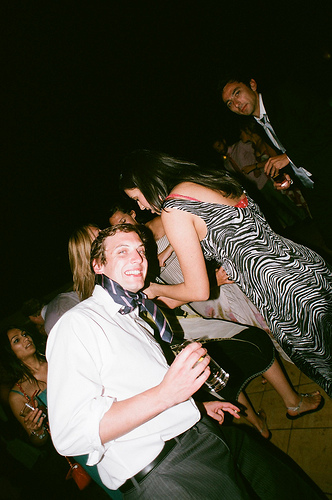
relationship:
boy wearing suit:
[37, 222, 326, 494] [44, 274, 330, 497]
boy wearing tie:
[37, 222, 326, 494] [92, 270, 173, 344]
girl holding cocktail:
[0, 325, 126, 497] [20, 400, 46, 418]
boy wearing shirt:
[45, 223, 326, 498] [43, 286, 208, 490]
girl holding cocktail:
[0, 325, 126, 497] [20, 400, 49, 425]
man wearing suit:
[213, 72, 331, 243] [259, 92, 331, 227]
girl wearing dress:
[118, 148, 332, 395] [160, 197, 328, 397]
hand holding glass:
[152, 341, 219, 412] [197, 363, 235, 396]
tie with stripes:
[94, 272, 175, 344] [158, 319, 170, 331]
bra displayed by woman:
[167, 191, 210, 209] [159, 179, 313, 287]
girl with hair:
[0, 325, 126, 497] [0, 351, 30, 374]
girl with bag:
[0, 325, 126, 497] [68, 461, 91, 490]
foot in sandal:
[305, 391, 322, 410] [290, 391, 321, 414]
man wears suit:
[216, 67, 332, 249] [255, 84, 331, 193]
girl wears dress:
[113, 143, 331, 361] [157, 171, 330, 376]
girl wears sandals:
[65, 221, 324, 420] [283, 387, 325, 415]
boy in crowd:
[45, 223, 326, 498] [10, 73, 329, 490]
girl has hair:
[118, 148, 332, 395] [114, 142, 246, 198]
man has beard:
[199, 128, 265, 173] [215, 146, 227, 159]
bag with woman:
[59, 463, 93, 493] [5, 329, 44, 447]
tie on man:
[135, 300, 178, 342] [201, 131, 253, 174]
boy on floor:
[45, 223, 326, 498] [264, 412, 330, 431]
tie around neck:
[94, 272, 175, 344] [100, 275, 152, 320]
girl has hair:
[118, 148, 332, 395] [130, 153, 187, 191]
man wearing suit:
[216, 67, 332, 249] [268, 102, 316, 180]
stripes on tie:
[150, 305, 162, 321] [125, 287, 185, 358]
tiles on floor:
[289, 416, 330, 480] [260, 398, 328, 432]